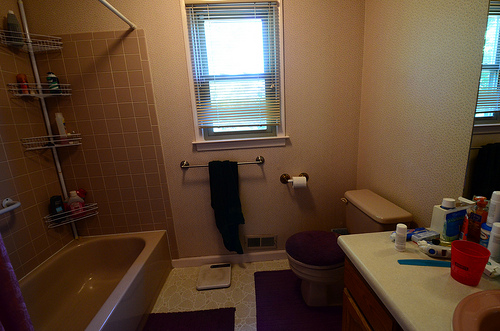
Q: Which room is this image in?
A: It is at the bathroom.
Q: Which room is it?
A: It is a bathroom.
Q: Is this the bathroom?
A: Yes, it is the bathroom.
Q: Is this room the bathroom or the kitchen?
A: It is the bathroom.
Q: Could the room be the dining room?
A: No, it is the bathroom.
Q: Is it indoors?
A: Yes, it is indoors.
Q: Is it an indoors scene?
A: Yes, it is indoors.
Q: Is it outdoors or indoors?
A: It is indoors.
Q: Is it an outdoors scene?
A: No, it is indoors.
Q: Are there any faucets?
A: No, there are no faucets.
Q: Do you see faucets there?
A: No, there are no faucets.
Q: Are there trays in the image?
A: No, there are no trays.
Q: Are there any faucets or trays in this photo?
A: No, there are no trays or faucets.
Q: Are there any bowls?
A: No, there are no bowls.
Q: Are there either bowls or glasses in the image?
A: No, there are no bowls or glasses.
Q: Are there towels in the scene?
A: Yes, there is a towel.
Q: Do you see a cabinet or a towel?
A: Yes, there is a towel.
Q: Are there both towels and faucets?
A: No, there is a towel but no faucets.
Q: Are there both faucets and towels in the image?
A: No, there is a towel but no faucets.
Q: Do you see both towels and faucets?
A: No, there is a towel but no faucets.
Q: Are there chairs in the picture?
A: No, there are no chairs.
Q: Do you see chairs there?
A: No, there are no chairs.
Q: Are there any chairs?
A: No, there are no chairs.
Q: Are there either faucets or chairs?
A: No, there are no chairs or faucets.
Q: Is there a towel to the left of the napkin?
A: Yes, there is a towel to the left of the napkin.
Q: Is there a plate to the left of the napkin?
A: No, there is a towel to the left of the napkin.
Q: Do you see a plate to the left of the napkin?
A: No, there is a towel to the left of the napkin.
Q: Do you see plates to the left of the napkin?
A: No, there is a towel to the left of the napkin.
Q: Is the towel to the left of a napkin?
A: Yes, the towel is to the left of a napkin.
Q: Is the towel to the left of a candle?
A: No, the towel is to the left of a napkin.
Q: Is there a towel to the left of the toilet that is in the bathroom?
A: Yes, there is a towel to the left of the toilet.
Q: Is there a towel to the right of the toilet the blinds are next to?
A: No, the towel is to the left of the toilet.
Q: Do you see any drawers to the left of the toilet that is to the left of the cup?
A: No, there is a towel to the left of the toilet.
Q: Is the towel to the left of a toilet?
A: Yes, the towel is to the left of a toilet.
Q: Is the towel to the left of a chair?
A: No, the towel is to the left of a toilet.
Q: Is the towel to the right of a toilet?
A: No, the towel is to the left of a toilet.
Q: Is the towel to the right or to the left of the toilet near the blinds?
A: The towel is to the left of the toilet.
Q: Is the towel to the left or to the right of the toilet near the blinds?
A: The towel is to the left of the toilet.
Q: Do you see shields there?
A: No, there are no shields.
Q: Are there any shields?
A: No, there are no shields.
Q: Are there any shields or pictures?
A: No, there are no shields or pictures.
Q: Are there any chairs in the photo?
A: No, there are no chairs.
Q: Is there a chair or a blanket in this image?
A: No, there are no chairs or blankets.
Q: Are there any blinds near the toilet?
A: Yes, there are blinds near the toilet.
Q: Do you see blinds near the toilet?
A: Yes, there are blinds near the toilet.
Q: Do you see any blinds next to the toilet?
A: Yes, there are blinds next to the toilet.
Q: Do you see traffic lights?
A: No, there are no traffic lights.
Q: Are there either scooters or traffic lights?
A: No, there are no traffic lights or scooters.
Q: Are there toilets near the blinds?
A: Yes, there is a toilet near the blinds.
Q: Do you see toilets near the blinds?
A: Yes, there is a toilet near the blinds.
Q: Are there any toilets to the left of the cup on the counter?
A: Yes, there is a toilet to the left of the cup.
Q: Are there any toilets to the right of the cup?
A: No, the toilet is to the left of the cup.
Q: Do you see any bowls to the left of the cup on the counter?
A: No, there is a toilet to the left of the cup.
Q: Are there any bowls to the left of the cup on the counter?
A: No, there is a toilet to the left of the cup.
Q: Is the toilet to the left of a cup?
A: Yes, the toilet is to the left of a cup.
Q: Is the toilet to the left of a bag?
A: No, the toilet is to the left of a cup.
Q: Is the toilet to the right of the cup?
A: No, the toilet is to the left of the cup.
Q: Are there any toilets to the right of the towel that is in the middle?
A: Yes, there is a toilet to the right of the towel.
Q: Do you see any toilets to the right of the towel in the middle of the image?
A: Yes, there is a toilet to the right of the towel.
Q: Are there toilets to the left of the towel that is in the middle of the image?
A: No, the toilet is to the right of the towel.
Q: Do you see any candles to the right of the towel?
A: No, there is a toilet to the right of the towel.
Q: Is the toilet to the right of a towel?
A: Yes, the toilet is to the right of a towel.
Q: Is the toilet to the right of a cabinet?
A: No, the toilet is to the right of a towel.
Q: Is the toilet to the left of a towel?
A: No, the toilet is to the right of a towel.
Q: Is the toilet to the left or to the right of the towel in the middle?
A: The toilet is to the right of the towel.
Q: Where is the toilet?
A: The toilet is in the bathroom.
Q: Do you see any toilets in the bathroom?
A: Yes, there is a toilet in the bathroom.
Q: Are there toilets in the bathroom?
A: Yes, there is a toilet in the bathroom.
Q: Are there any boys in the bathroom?
A: No, there is a toilet in the bathroom.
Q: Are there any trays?
A: No, there are no trays.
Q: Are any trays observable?
A: No, there are no trays.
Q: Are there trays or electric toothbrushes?
A: No, there are no trays or electric toothbrushes.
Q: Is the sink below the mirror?
A: Yes, the sink is below the mirror.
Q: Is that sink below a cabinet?
A: No, the sink is below the mirror.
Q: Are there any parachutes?
A: No, there are no parachutes.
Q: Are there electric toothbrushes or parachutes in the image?
A: No, there are no parachutes or electric toothbrushes.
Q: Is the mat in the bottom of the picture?
A: Yes, the mat is in the bottom of the image.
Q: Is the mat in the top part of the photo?
A: No, the mat is in the bottom of the image.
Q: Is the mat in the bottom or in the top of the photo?
A: The mat is in the bottom of the image.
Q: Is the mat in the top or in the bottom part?
A: The mat is in the bottom of the image.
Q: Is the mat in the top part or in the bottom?
A: The mat is in the bottom of the image.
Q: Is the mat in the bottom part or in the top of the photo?
A: The mat is in the bottom of the image.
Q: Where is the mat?
A: The mat is in the bathroom.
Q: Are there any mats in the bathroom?
A: Yes, there is a mat in the bathroom.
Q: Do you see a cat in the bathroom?
A: No, there is a mat in the bathroom.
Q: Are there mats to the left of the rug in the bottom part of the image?
A: Yes, there is a mat to the left of the rug.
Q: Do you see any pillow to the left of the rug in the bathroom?
A: No, there is a mat to the left of the rug.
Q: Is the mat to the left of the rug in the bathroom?
A: Yes, the mat is to the left of the rug.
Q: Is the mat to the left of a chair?
A: No, the mat is to the left of the rug.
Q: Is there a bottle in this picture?
A: Yes, there is a bottle.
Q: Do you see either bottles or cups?
A: Yes, there is a bottle.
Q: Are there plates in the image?
A: No, there are no plates.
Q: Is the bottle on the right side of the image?
A: Yes, the bottle is on the right of the image.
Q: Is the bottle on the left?
A: No, the bottle is on the right of the image.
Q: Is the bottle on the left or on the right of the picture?
A: The bottle is on the right of the image.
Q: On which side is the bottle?
A: The bottle is on the right of the image.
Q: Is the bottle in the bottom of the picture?
A: Yes, the bottle is in the bottom of the image.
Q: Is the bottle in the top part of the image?
A: No, the bottle is in the bottom of the image.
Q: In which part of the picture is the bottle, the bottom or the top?
A: The bottle is in the bottom of the image.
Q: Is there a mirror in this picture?
A: Yes, there is a mirror.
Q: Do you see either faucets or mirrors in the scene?
A: Yes, there is a mirror.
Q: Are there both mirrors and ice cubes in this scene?
A: No, there is a mirror but no ice cubes.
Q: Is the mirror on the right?
A: Yes, the mirror is on the right of the image.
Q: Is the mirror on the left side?
A: No, the mirror is on the right of the image.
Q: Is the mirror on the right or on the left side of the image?
A: The mirror is on the right of the image.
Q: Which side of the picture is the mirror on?
A: The mirror is on the right of the image.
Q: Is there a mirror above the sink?
A: Yes, there is a mirror above the sink.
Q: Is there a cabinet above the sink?
A: No, there is a mirror above the sink.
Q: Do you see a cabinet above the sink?
A: No, there is a mirror above the sink.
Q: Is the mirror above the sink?
A: Yes, the mirror is above the sink.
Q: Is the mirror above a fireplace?
A: No, the mirror is above the sink.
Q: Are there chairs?
A: No, there are no chairs.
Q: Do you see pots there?
A: No, there are no pots.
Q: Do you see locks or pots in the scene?
A: No, there are no pots or locks.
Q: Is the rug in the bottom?
A: Yes, the rug is in the bottom of the image.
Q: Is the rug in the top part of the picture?
A: No, the rug is in the bottom of the image.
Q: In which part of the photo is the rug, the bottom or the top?
A: The rug is in the bottom of the image.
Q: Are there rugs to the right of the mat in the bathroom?
A: Yes, there is a rug to the right of the mat.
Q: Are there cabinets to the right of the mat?
A: No, there is a rug to the right of the mat.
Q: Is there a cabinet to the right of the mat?
A: No, there is a rug to the right of the mat.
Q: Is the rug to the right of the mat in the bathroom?
A: Yes, the rug is to the right of the mat.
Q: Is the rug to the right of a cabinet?
A: No, the rug is to the right of the mat.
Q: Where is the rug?
A: The rug is in the bathroom.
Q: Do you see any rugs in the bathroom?
A: Yes, there is a rug in the bathroom.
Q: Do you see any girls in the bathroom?
A: No, there is a rug in the bathroom.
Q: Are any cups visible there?
A: Yes, there is a cup.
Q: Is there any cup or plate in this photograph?
A: Yes, there is a cup.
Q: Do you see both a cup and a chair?
A: No, there is a cup but no chairs.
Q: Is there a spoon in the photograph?
A: No, there are no spoons.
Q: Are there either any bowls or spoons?
A: No, there are no spoons or bowls.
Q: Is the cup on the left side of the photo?
A: No, the cup is on the right of the image.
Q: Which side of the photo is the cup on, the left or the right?
A: The cup is on the right of the image.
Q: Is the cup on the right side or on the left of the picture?
A: The cup is on the right of the image.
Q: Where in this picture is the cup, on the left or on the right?
A: The cup is on the right of the image.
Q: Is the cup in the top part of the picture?
A: No, the cup is in the bottom of the image.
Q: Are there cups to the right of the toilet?
A: Yes, there is a cup to the right of the toilet.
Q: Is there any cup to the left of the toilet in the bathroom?
A: No, the cup is to the right of the toilet.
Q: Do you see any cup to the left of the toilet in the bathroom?
A: No, the cup is to the right of the toilet.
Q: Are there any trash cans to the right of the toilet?
A: No, there is a cup to the right of the toilet.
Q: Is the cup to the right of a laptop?
A: No, the cup is to the right of the toilet.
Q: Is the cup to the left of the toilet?
A: No, the cup is to the right of the toilet.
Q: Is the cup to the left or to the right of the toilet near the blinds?
A: The cup is to the right of the toilet.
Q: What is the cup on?
A: The cup is on the counter.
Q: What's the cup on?
A: The cup is on the counter.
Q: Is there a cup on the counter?
A: Yes, there is a cup on the counter.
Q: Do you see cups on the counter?
A: Yes, there is a cup on the counter.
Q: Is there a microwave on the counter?
A: No, there is a cup on the counter.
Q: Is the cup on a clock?
A: No, the cup is on the counter.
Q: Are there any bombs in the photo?
A: No, there are no bombs.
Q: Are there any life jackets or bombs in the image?
A: No, there are no bombs or life jackets.